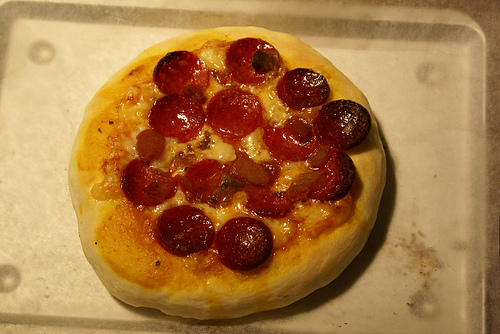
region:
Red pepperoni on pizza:
[154, 44, 211, 91]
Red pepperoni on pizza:
[219, 28, 276, 87]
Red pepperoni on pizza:
[275, 56, 321, 110]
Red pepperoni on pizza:
[310, 111, 380, 158]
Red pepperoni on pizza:
[222, 217, 282, 272]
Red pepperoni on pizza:
[152, 217, 245, 252]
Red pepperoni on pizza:
[120, 156, 190, 211]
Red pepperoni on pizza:
[248, 174, 295, 216]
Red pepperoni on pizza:
[206, 83, 263, 138]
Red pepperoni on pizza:
[184, 151, 223, 193]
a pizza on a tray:
[65, 30, 397, 325]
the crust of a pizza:
[75, 165, 110, 235]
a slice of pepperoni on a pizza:
[207, 206, 282, 283]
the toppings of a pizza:
[185, 141, 308, 230]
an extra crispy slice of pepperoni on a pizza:
[313, 94, 373, 157]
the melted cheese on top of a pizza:
[201, 134, 233, 159]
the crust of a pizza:
[271, 244, 356, 306]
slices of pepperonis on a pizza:
[152, 59, 210, 136]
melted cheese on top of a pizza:
[279, 204, 333, 244]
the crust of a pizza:
[93, 92, 139, 127]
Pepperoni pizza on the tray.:
[75, 28, 383, 323]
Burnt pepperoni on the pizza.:
[312, 98, 372, 146]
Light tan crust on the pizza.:
[67, 24, 386, 326]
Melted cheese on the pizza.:
[192, 130, 238, 165]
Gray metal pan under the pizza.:
[3, 3, 495, 330]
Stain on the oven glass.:
[400, 217, 445, 294]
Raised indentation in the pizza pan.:
[26, 37, 51, 62]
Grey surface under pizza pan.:
[356, 0, 496, 330]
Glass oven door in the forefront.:
[0, 0, 496, 330]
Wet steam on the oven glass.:
[339, 1, 478, 75]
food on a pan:
[80, 22, 382, 318]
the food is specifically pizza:
[68, 26, 394, 312]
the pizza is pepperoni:
[81, 10, 390, 312]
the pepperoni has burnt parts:
[291, 68, 376, 193]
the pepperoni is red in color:
[130, 45, 363, 272]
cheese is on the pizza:
[123, 45, 370, 280]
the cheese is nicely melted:
[150, 30, 355, 274]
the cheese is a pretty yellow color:
[121, 41, 359, 271]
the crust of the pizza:
[67, 23, 382, 308]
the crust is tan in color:
[58, 28, 393, 320]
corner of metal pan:
[425, 5, 495, 122]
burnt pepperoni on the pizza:
[321, 97, 375, 148]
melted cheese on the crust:
[114, 236, 150, 286]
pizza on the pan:
[83, 18, 405, 320]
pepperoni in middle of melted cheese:
[207, 83, 264, 150]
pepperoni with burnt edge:
[210, 213, 278, 275]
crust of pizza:
[73, 209, 127, 331]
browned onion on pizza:
[134, 122, 170, 166]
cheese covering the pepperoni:
[260, 103, 321, 163]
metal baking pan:
[405, 5, 496, 215]